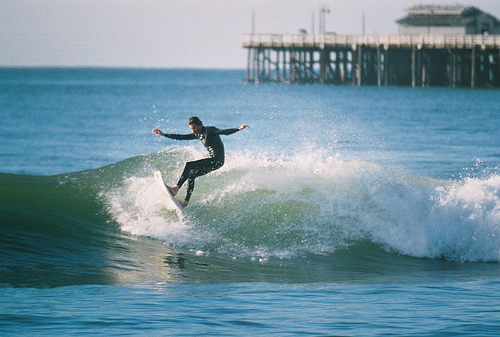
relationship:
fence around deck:
[238, 27, 488, 51] [240, 0, 488, 94]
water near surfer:
[1, 65, 500, 337] [153, 115, 249, 211]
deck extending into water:
[240, 0, 499, 86] [1, 65, 498, 333]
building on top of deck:
[393, 2, 499, 35] [234, 31, 484, 48]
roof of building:
[399, 3, 492, 35] [393, 2, 484, 33]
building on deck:
[393, 2, 484, 33] [242, 27, 483, 94]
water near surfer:
[1, 65, 498, 333] [153, 115, 249, 211]